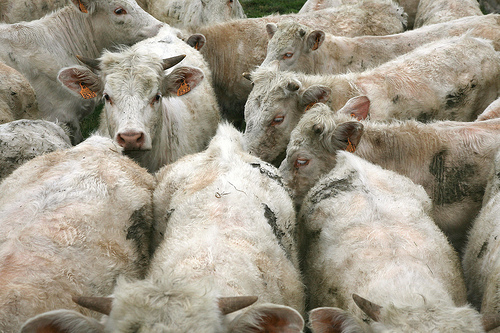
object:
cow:
[0, 0, 183, 145]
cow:
[240, 36, 500, 165]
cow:
[277, 95, 500, 231]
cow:
[56, 22, 221, 174]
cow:
[253, 13, 500, 76]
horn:
[75, 54, 101, 70]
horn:
[162, 54, 186, 70]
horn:
[313, 124, 323, 133]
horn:
[288, 82, 299, 91]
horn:
[241, 72, 252, 82]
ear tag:
[78, 82, 97, 100]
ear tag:
[176, 79, 191, 96]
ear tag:
[346, 137, 356, 154]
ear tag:
[304, 102, 316, 111]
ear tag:
[312, 38, 318, 51]